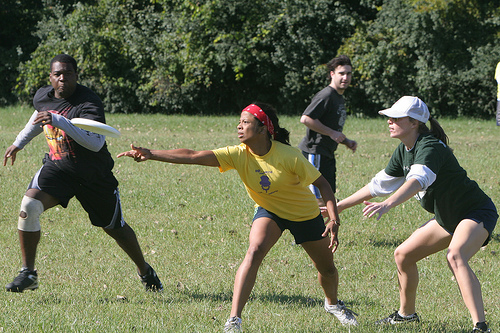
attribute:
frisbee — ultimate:
[71, 115, 126, 140]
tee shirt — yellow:
[205, 138, 331, 221]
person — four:
[9, 52, 159, 301]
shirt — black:
[296, 85, 349, 153]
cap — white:
[379, 96, 439, 128]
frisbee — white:
[54, 112, 132, 152]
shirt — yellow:
[211, 137, 326, 224]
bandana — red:
[238, 100, 273, 137]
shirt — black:
[32, 85, 116, 175]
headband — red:
[242, 102, 273, 138]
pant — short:
[251, 207, 327, 244]